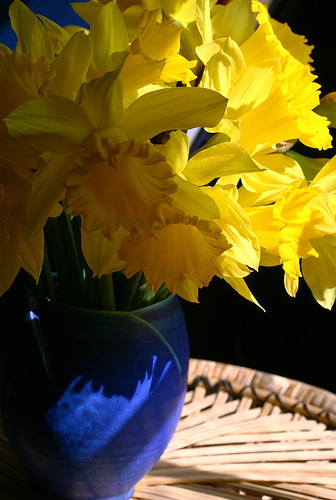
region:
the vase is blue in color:
[78, 417, 126, 457]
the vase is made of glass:
[77, 425, 160, 476]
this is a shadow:
[84, 340, 124, 369]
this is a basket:
[219, 397, 276, 461]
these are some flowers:
[42, 33, 328, 238]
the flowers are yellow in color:
[243, 85, 300, 197]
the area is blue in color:
[58, 9, 68, 17]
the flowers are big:
[195, 190, 281, 241]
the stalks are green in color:
[75, 273, 119, 297]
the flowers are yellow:
[32, 75, 296, 307]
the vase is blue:
[63, 304, 195, 497]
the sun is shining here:
[170, 154, 328, 394]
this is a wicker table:
[225, 403, 324, 485]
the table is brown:
[221, 397, 326, 485]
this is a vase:
[37, 349, 165, 481]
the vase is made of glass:
[12, 351, 120, 428]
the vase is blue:
[31, 336, 145, 430]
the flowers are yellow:
[42, 142, 264, 265]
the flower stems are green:
[51, 223, 172, 345]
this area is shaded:
[30, 132, 144, 432]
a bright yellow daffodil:
[24, 75, 226, 269]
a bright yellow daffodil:
[112, 132, 255, 302]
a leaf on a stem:
[118, 87, 226, 140]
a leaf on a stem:
[186, 141, 269, 187]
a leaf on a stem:
[221, 274, 264, 314]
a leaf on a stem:
[10, 209, 46, 282]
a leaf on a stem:
[69, 221, 123, 277]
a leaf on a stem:
[25, 151, 78, 237]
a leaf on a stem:
[9, 1, 54, 66]